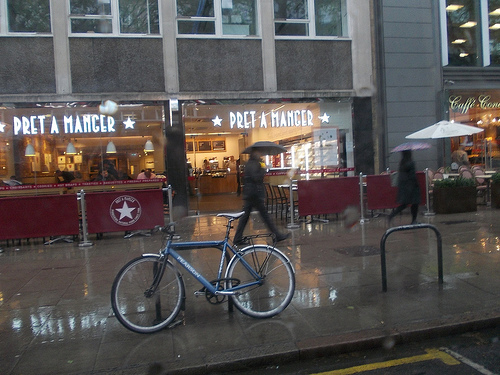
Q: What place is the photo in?
A: It is at the sidewalk.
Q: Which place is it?
A: It is a sidewalk.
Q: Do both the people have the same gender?
A: No, they are both male and female.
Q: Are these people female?
A: No, they are both male and female.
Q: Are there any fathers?
A: No, there are no fathers.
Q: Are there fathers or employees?
A: No, there are no fathers or employees.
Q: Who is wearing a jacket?
A: The man is wearing a jacket.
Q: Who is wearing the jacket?
A: The man is wearing a jacket.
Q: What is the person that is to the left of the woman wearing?
A: The man is wearing a jacket.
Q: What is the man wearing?
A: The man is wearing a jacket.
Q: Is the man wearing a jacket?
A: Yes, the man is wearing a jacket.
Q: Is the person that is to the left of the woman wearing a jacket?
A: Yes, the man is wearing a jacket.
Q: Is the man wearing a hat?
A: No, the man is wearing a jacket.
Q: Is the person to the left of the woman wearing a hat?
A: No, the man is wearing a jacket.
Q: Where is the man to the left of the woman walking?
A: The man is walking on the side walk.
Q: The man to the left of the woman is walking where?
A: The man is walking on the side walk.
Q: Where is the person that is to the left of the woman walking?
A: The man is walking on the side walk.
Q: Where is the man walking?
A: The man is walking on the side walk.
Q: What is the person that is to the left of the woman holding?
A: The man is holding the umbrella.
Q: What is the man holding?
A: The man is holding the umbrella.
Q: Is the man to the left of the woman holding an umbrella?
A: Yes, the man is holding an umbrella.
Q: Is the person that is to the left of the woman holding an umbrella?
A: Yes, the man is holding an umbrella.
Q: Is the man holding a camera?
A: No, the man is holding an umbrella.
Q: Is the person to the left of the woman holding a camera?
A: No, the man is holding an umbrella.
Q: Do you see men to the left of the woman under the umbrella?
A: Yes, there is a man to the left of the woman.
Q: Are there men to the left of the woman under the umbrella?
A: Yes, there is a man to the left of the woman.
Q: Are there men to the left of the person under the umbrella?
A: Yes, there is a man to the left of the woman.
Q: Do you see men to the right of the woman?
A: No, the man is to the left of the woman.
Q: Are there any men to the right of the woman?
A: No, the man is to the left of the woman.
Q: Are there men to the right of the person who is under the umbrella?
A: No, the man is to the left of the woman.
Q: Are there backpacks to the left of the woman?
A: No, there is a man to the left of the woman.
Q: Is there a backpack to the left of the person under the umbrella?
A: No, there is a man to the left of the woman.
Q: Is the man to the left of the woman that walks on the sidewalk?
A: Yes, the man is to the left of the woman.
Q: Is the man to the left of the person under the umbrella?
A: Yes, the man is to the left of the woman.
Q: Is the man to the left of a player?
A: No, the man is to the left of the woman.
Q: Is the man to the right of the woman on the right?
A: No, the man is to the left of the woman.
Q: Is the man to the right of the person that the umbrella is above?
A: No, the man is to the left of the woman.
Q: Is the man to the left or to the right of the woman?
A: The man is to the left of the woman.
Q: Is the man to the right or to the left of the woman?
A: The man is to the left of the woman.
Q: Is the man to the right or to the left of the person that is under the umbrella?
A: The man is to the left of the woman.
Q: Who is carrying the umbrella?
A: The man is carrying the umbrella.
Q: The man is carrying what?
A: The man is carrying an umbrella.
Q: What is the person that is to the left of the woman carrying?
A: The man is carrying an umbrella.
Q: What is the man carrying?
A: The man is carrying an umbrella.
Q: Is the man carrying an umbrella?
A: Yes, the man is carrying an umbrella.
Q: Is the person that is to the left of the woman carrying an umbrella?
A: Yes, the man is carrying an umbrella.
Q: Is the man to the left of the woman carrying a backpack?
A: No, the man is carrying an umbrella.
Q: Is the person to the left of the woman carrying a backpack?
A: No, the man is carrying an umbrella.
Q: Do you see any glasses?
A: No, there are no glasses.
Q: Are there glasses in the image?
A: No, there are no glasses.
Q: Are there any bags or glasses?
A: No, there are no glasses or bags.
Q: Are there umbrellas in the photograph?
A: Yes, there is an umbrella.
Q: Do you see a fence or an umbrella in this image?
A: Yes, there is an umbrella.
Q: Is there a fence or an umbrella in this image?
A: Yes, there is an umbrella.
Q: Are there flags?
A: No, there are no flags.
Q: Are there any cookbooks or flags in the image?
A: No, there are no flags or cookbooks.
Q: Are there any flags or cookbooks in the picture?
A: No, there are no flags or cookbooks.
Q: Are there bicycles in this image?
A: Yes, there is a bicycle.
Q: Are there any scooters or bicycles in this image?
A: Yes, there is a bicycle.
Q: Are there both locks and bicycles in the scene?
A: No, there is a bicycle but no locks.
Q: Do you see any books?
A: No, there are no books.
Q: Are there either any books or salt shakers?
A: No, there are no books or salt shakers.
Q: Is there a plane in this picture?
A: No, there are no airplanes.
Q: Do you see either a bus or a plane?
A: No, there are no airplanes or buses.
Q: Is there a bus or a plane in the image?
A: No, there are no airplanes or buses.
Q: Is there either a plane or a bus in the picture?
A: No, there are no airplanes or buses.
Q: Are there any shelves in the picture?
A: No, there are no shelves.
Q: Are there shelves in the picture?
A: No, there are no shelves.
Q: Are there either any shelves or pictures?
A: No, there are no shelves or pictures.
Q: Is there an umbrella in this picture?
A: Yes, there is an umbrella.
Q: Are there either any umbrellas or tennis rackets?
A: Yes, there is an umbrella.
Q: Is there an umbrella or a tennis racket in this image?
A: Yes, there is an umbrella.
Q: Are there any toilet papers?
A: No, there are no toilet papers.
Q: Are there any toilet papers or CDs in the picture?
A: No, there are no toilet papers or cds.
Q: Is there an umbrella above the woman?
A: Yes, there is an umbrella above the woman.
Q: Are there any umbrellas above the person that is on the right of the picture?
A: Yes, there is an umbrella above the woman.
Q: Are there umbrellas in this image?
A: Yes, there is an umbrella.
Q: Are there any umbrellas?
A: Yes, there is an umbrella.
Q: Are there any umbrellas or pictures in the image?
A: Yes, there is an umbrella.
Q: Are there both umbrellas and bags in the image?
A: No, there is an umbrella but no bags.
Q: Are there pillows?
A: No, there are no pillows.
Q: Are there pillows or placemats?
A: No, there are no pillows or placemats.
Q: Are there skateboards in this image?
A: No, there are no skateboards.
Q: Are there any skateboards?
A: No, there are no skateboards.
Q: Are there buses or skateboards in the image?
A: No, there are no skateboards or buses.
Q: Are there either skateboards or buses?
A: No, there are no skateboards or buses.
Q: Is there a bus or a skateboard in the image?
A: No, there are no skateboards or buses.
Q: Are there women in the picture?
A: Yes, there is a woman.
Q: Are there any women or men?
A: Yes, there is a woman.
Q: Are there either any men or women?
A: Yes, there is a woman.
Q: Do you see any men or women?
A: Yes, there is a woman.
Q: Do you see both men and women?
A: Yes, there are both a woman and a man.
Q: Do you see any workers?
A: No, there are no workers.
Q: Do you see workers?
A: No, there are no workers.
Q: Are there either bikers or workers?
A: No, there are no workers or bikers.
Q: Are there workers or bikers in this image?
A: No, there are no workers or bikers.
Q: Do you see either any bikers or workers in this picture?
A: No, there are no workers or bikers.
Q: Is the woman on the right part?
A: Yes, the woman is on the right of the image.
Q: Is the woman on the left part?
A: No, the woman is on the right of the image.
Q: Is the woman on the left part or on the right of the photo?
A: The woman is on the right of the image.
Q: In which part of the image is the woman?
A: The woman is on the right of the image.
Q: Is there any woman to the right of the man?
A: Yes, there is a woman to the right of the man.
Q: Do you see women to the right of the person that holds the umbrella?
A: Yes, there is a woman to the right of the man.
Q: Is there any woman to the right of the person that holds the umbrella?
A: Yes, there is a woman to the right of the man.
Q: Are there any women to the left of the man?
A: No, the woman is to the right of the man.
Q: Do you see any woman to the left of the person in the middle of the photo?
A: No, the woman is to the right of the man.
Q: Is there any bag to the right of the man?
A: No, there is a woman to the right of the man.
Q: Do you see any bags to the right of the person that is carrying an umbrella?
A: No, there is a woman to the right of the man.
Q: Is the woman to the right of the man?
A: Yes, the woman is to the right of the man.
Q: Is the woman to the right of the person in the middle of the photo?
A: Yes, the woman is to the right of the man.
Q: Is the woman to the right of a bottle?
A: No, the woman is to the right of the man.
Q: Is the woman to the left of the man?
A: No, the woman is to the right of the man.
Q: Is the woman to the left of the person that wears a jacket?
A: No, the woman is to the right of the man.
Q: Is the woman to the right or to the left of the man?
A: The woman is to the right of the man.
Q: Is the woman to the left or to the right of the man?
A: The woman is to the right of the man.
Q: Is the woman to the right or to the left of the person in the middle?
A: The woman is to the right of the man.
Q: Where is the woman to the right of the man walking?
A: The woman is walking on the sidewalk.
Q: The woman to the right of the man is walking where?
A: The woman is walking on the sidewalk.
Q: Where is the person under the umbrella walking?
A: The woman is walking on the sidewalk.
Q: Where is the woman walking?
A: The woman is walking on the sidewalk.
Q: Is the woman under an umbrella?
A: Yes, the woman is under an umbrella.